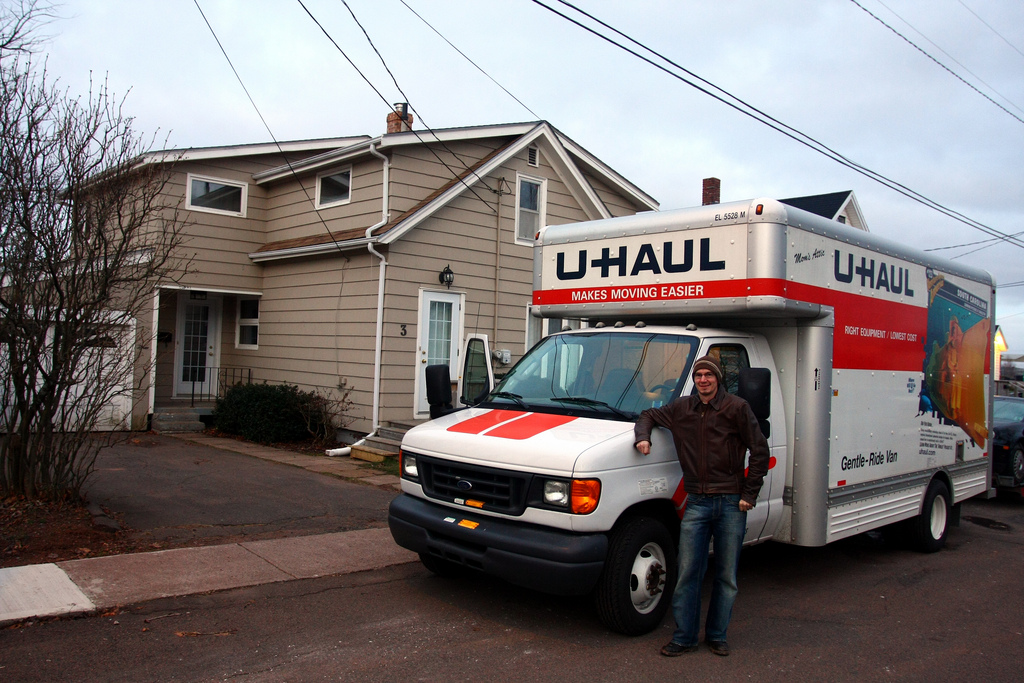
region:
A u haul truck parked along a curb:
[382, 195, 1006, 636]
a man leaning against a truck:
[630, 347, 777, 671]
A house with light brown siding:
[3, 115, 668, 553]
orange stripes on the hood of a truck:
[442, 391, 583, 456]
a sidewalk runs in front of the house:
[1, 504, 428, 628]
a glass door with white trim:
[407, 274, 474, 427]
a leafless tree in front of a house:
[4, 1, 201, 492]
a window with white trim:
[178, 166, 256, 224]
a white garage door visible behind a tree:
[4, 293, 147, 443]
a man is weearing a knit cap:
[686, 353, 728, 402]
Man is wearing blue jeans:
[610, 340, 776, 655]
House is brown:
[17, 86, 593, 501]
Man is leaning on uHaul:
[373, 191, 1007, 606]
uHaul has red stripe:
[394, 187, 990, 615]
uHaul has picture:
[858, 245, 1005, 455]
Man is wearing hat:
[672, 332, 727, 387]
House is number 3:
[368, 307, 413, 343]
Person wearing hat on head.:
[688, 353, 728, 391]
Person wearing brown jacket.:
[635, 395, 768, 506]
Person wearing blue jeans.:
[675, 473, 749, 623]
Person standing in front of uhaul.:
[603, 342, 784, 617]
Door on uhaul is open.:
[443, 329, 542, 447]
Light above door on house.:
[435, 258, 464, 301]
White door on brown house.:
[417, 287, 459, 406]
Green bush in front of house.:
[223, 373, 334, 435]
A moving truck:
[399, 183, 995, 637]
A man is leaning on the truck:
[633, 345, 767, 668]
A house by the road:
[8, 114, 672, 468]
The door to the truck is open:
[425, 319, 509, 447]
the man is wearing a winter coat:
[622, 348, 777, 661]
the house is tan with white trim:
[12, 114, 660, 454]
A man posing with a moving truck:
[385, 186, 1002, 665]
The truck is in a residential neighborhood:
[388, 197, 1009, 641]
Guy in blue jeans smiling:
[624, 352, 773, 662]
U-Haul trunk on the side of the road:
[1, 184, 1022, 679]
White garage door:
[0, 312, 138, 436]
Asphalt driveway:
[16, 428, 389, 550]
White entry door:
[411, 289, 469, 419]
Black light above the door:
[409, 257, 471, 420]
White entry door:
[168, 292, 223, 395]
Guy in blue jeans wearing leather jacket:
[627, 348, 777, 661]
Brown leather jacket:
[628, 383, 777, 504]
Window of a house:
[517, 181, 544, 242]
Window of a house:
[315, 162, 351, 210]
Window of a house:
[185, 170, 253, 218]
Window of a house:
[233, 290, 265, 351]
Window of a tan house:
[518, 179, 547, 247]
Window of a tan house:
[313, 164, 351, 204]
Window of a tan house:
[189, 168, 247, 219]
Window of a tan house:
[233, 294, 263, 348]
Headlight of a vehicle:
[534, 471, 598, 516]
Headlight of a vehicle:
[397, 445, 421, 484]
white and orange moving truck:
[403, 189, 1020, 619]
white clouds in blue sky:
[131, 31, 195, 80]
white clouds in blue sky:
[359, 7, 461, 80]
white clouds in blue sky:
[743, 31, 842, 98]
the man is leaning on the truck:
[612, 336, 772, 654]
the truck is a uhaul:
[374, 187, 1001, 640]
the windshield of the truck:
[488, 320, 688, 410]